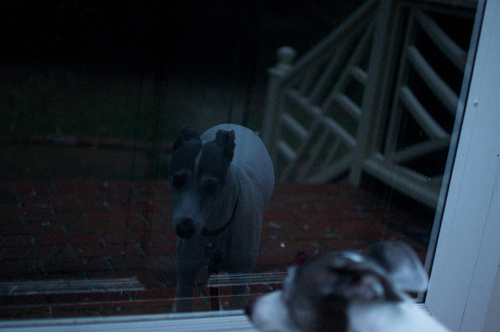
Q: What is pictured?
A: A dog.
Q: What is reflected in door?
A: A dog.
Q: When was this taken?
A: Maybe dusk.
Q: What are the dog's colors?
A: White and black.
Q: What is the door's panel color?
A: White.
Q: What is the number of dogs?
A: One.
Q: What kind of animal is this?
A: Dog.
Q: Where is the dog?
A: In front of window.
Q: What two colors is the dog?
A: White and brown.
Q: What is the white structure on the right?
A: Step handrail.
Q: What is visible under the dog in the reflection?
A: Brick.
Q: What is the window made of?
A: Glass.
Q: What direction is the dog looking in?
A: Left.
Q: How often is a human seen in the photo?
A: Not at all.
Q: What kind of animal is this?
A: Dog.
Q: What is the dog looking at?
A: A window.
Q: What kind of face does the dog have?
A: Brown and white face with narrow snout.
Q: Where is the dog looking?
A: Through a window.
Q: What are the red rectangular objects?
A: Bricks.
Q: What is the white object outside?
A: A handrail.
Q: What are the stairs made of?
A: Bricks.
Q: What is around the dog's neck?
A: Collar.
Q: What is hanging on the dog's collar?
A: Tags.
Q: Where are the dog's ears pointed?
A: Back.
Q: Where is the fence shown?
A: In reflection.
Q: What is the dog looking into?
A: A window.